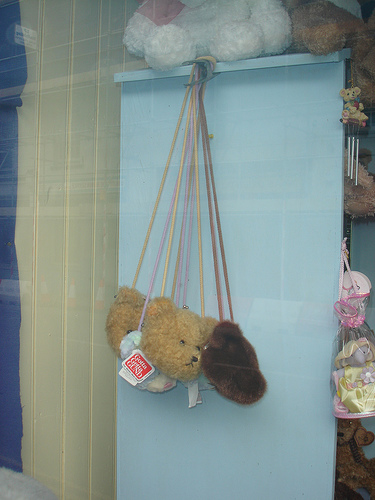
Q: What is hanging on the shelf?
A: Stuffed animal purses.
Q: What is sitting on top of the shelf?
A: Stuffed bears.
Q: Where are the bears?
A: On the blue shelf.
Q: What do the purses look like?
A: Bear heads.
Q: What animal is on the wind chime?
A: A bear.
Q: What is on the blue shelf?
A: Lots of bears.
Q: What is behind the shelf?
A: A paneled wall.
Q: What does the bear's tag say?
A: Gotta Getta Gund.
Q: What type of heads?
A: Heads of stuffed animals.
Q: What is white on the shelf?
A: The teddy bear.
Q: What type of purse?
A: A teddy bear purse.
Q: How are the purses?
A: The purse are for sale.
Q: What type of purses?
A: Teddy bear purses.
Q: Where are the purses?
A: On the wall.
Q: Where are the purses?
A: Four on the wall.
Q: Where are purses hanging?
A: From the shelf.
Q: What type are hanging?
A: Four teddy bear purses.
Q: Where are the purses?
A: Hanging from the shelf.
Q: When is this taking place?
A: Daytime.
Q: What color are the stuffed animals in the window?
A: Tan and brown.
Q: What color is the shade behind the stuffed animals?
A: Blue.